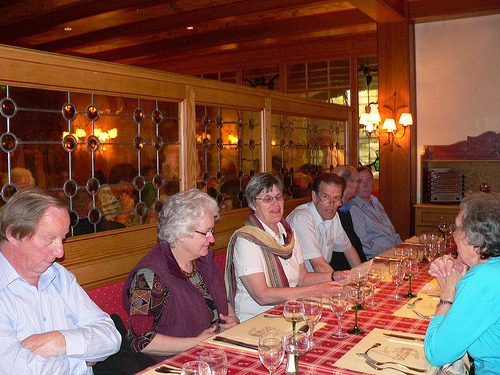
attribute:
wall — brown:
[374, 22, 417, 239]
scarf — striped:
[235, 211, 299, 286]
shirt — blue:
[0, 242, 125, 373]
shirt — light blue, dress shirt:
[2, 253, 122, 373]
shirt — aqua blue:
[421, 257, 498, 374]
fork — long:
[363, 350, 393, 365]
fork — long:
[363, 357, 388, 371]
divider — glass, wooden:
[0, 44, 361, 293]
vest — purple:
[125, 240, 230, 320]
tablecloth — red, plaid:
[127, 233, 472, 374]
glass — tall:
[248, 327, 289, 371]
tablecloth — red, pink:
[257, 198, 439, 373]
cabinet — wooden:
[420, 155, 498, 232]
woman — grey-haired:
[114, 181, 247, 365]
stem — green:
[405, 277, 415, 298]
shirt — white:
[285, 201, 355, 282]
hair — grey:
[137, 187, 187, 267]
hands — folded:
[417, 257, 499, 310]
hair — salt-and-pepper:
[244, 170, 289, 199]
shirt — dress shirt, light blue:
[0, 267, 118, 371]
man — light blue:
[1, 176, 126, 367]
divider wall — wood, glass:
[2, 45, 362, 302]